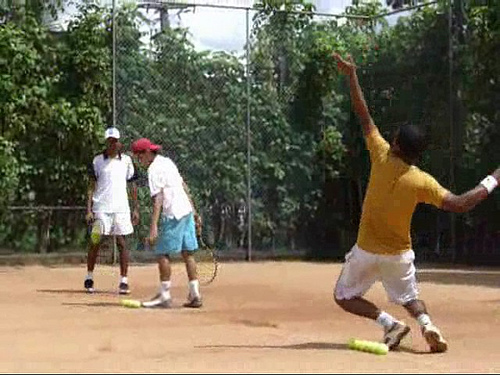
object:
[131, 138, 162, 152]
cap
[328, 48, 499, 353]
man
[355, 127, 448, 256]
shirt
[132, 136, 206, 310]
man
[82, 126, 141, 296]
man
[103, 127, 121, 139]
cap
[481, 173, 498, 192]
sweat band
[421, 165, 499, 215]
arm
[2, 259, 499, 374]
tennis court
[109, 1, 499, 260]
fence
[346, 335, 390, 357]
tennis balls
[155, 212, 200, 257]
shorts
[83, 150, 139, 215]
shirt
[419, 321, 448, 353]
shoes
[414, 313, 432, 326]
socks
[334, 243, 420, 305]
shorts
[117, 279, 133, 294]
shoes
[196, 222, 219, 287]
tennis racket